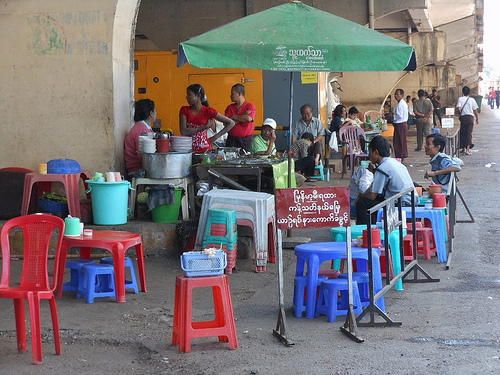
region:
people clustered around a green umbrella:
[123, 3, 478, 223]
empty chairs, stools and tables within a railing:
[11, 185, 429, 355]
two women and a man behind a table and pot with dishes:
[125, 70, 257, 182]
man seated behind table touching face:
[251, 95, 286, 180]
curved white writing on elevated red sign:
[267, 166, 363, 346]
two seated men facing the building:
[345, 112, 480, 253]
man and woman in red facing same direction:
[170, 70, 260, 155]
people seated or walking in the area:
[330, 67, 490, 177]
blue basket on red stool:
[172, 241, 242, 366]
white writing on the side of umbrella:
[215, 32, 360, 74]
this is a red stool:
[164, 275, 241, 372]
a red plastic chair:
[3, 202, 86, 366]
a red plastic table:
[36, 202, 163, 317]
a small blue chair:
[318, 274, 363, 321]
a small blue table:
[291, 230, 396, 323]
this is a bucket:
[83, 180, 138, 231]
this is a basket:
[183, 241, 231, 281]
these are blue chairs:
[61, 251, 147, 308]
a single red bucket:
[358, 221, 390, 251]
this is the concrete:
[469, 325, 486, 347]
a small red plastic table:
[59, 206, 158, 308]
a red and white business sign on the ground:
[261, 164, 378, 368]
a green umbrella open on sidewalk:
[150, 7, 432, 219]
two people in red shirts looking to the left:
[173, 69, 266, 148]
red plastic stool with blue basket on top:
[161, 235, 252, 371]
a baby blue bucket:
[78, 160, 135, 232]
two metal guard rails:
[354, 164, 484, 320]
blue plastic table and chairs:
[296, 231, 387, 331]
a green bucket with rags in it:
[135, 180, 202, 213]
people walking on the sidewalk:
[384, 60, 485, 152]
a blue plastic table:
[284, 236, 401, 323]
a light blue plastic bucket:
[85, 173, 139, 226]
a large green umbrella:
[174, 2, 416, 73]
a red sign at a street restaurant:
[269, 185, 364, 233]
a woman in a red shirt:
[181, 100, 223, 153]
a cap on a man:
[258, 119, 276, 137]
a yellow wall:
[132, 48, 265, 162]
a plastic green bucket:
[144, 185, 196, 220]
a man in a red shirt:
[229, 80, 253, 145]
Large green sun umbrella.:
[144, 0, 435, 87]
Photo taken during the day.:
[2, 29, 493, 370]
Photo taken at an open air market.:
[16, 0, 495, 367]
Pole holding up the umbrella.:
[272, 58, 304, 242]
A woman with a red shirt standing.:
[163, 77, 238, 157]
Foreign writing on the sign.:
[230, 171, 361, 233]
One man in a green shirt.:
[235, 105, 295, 157]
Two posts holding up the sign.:
[250, 215, 370, 345]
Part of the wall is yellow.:
[106, 30, 277, 153]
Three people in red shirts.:
[115, 65, 260, 184]